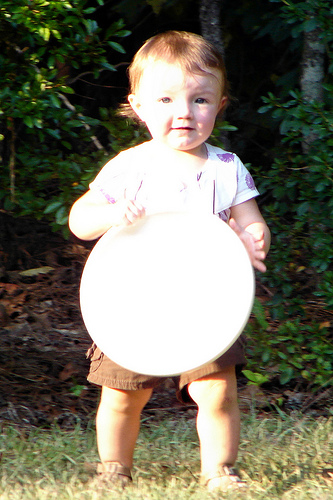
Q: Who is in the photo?
A: A toddler.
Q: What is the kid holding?
A: Frisbee.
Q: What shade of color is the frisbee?
A: White.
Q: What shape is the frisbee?
A: Round.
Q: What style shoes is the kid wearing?
A: Sandals.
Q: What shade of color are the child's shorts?
A: Brown.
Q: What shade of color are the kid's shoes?
A: Brown.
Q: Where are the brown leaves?
A: On ground behind child.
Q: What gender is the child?
A: Female.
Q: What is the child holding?
A: Frisbee.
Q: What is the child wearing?
A: T-shirt and shorts.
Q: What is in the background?
A: Trees.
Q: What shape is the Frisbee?
A: Round.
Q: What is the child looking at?
A: The camera.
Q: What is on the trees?
A: Green leaves.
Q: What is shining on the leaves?
A: Sun.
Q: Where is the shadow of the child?
A: Right side of the child.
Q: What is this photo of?
A: A baby holding a frisbee.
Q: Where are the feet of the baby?
A: On the grass.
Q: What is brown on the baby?
A: The shorts.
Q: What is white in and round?
A: The frisbee.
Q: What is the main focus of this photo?
A: A toddler with a frisbee.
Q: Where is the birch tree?
A: In the woods.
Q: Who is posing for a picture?
A: A child.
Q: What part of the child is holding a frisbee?
A: The hand.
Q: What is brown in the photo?
A: Part of the child's shorts.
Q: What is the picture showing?
A: A baby holding a frisbee.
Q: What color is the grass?
A: Green.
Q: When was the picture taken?
A: During the day.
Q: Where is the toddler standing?
A: On the grass.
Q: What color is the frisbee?
A: White.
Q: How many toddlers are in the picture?
A: One.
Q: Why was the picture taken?
A: To capture the toddler.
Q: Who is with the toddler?
A: No one.